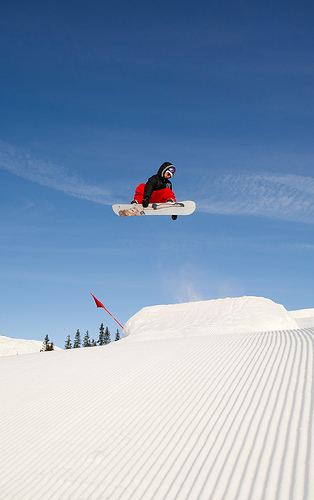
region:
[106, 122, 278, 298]
Man on the snow board.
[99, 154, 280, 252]
Person in the air.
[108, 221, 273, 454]
Snow on the hill.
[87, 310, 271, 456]
Tracks on the ground.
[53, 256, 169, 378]
Red flag on the snow.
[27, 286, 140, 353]
Flag in the snow.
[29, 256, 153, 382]
Trees in the background.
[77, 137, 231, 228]
White snow board.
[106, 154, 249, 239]
man in a pair of red pants.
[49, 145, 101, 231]
Clouds in the sky.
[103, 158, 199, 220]
a man snowboarding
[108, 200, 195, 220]
a snowboard with a woman on it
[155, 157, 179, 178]
the head of a man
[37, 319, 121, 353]
a group of trees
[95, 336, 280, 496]
a slope of raked snow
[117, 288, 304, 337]
a snowboard jump made of snow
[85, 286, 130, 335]
a red flag buried in the snow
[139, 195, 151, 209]
the hand of a man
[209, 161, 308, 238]
whispy clouds in the sky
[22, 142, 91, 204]
whispy clouds in the sky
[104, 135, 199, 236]
snow boarder in air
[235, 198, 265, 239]
white clouds in blue sky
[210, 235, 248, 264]
white clouds in blue sky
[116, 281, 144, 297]
white clouds in blue sky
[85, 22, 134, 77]
white clouds in blue sky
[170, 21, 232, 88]
white clouds in blue sky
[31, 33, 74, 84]
white clouds in blue sky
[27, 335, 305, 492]
The ground is covered in snow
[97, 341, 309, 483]
There are tons of lines on the ground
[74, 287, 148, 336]
A red flag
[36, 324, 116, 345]
A group of green trees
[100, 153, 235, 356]
The boy is many feet above the snow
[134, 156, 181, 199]
The boy is wearing a hooded sweatshirt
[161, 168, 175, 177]
The boy is wearing sunglasses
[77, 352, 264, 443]
tracks on the snow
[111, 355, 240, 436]
white snow on the ground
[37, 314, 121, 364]
trees in the distance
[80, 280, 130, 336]
red object in photo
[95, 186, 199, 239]
snowboard in the air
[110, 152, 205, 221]
man in the air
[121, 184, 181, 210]
orange pants on player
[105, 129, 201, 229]
man in air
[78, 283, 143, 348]
red flag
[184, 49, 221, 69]
white clouds in blue sky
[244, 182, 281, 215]
white clouds in blue sky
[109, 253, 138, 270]
white clouds in blue sky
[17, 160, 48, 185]
white clouds in blue sky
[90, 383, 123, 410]
white snow on hill side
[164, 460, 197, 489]
white snow on hill side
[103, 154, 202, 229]
person on snowboard in air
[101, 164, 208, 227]
person on snowboard in air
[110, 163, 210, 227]
person on snowboard in air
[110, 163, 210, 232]
person on snowboard in air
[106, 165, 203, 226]
person on snowboard in air